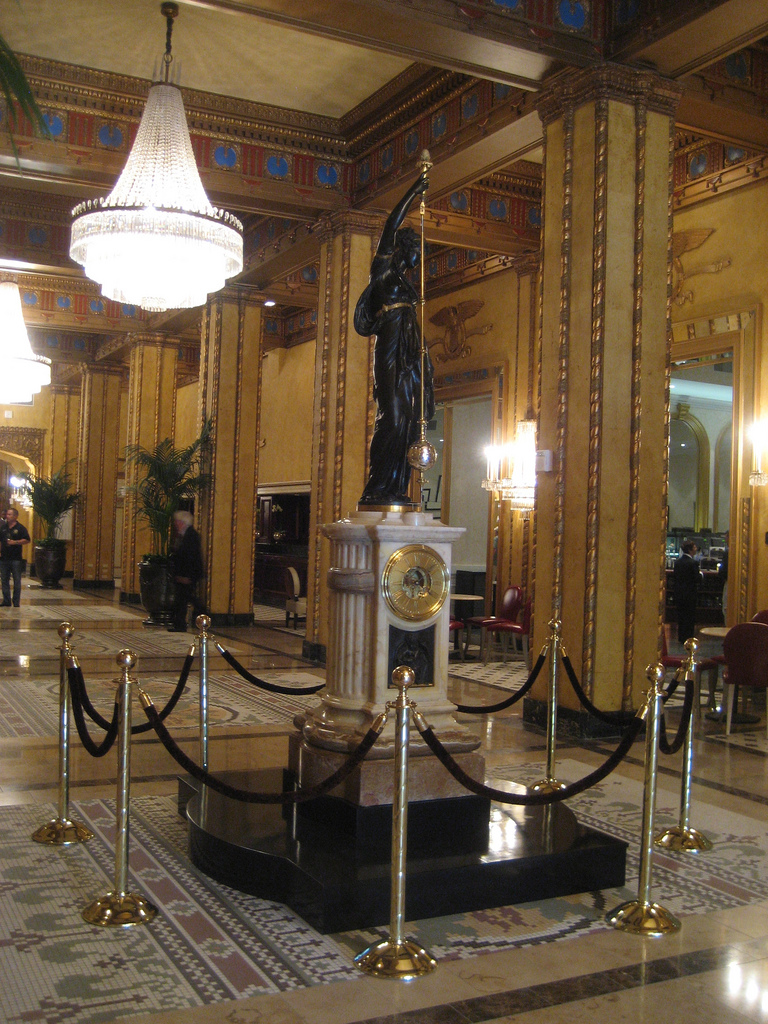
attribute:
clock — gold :
[385, 544, 450, 624]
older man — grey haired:
[168, 501, 200, 633]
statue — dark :
[325, 141, 470, 741]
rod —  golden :
[403, 144, 449, 473]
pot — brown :
[128, 550, 215, 631]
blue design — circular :
[29, 104, 77, 135]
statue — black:
[353, 139, 442, 513]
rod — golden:
[406, 139, 443, 480]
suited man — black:
[667, 536, 708, 651]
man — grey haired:
[163, 510, 205, 630]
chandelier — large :
[67, 0, 252, 317]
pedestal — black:
[320, 506, 464, 738]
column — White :
[321, 505, 466, 738]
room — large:
[0, 2, 742, 1015]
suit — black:
[169, 533, 219, 590]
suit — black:
[659, 544, 726, 651]